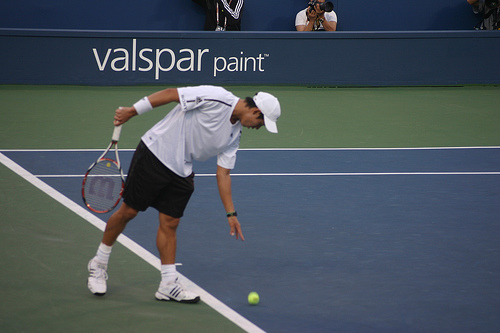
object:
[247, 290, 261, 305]
ball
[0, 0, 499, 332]
court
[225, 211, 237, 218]
watch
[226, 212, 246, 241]
hand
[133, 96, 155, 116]
wristband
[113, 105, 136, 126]
hand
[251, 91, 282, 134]
cap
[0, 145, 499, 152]
lines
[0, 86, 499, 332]
pavement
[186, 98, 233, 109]
stripe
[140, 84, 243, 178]
shirt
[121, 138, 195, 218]
shorts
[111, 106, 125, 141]
grip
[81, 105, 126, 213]
racket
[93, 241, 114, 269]
sock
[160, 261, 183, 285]
sock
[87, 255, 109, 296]
shoe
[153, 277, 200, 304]
shoe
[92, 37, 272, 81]
sign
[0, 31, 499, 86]
wall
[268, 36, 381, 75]
valspar paint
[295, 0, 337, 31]
man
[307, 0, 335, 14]
camera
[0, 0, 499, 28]
side of court